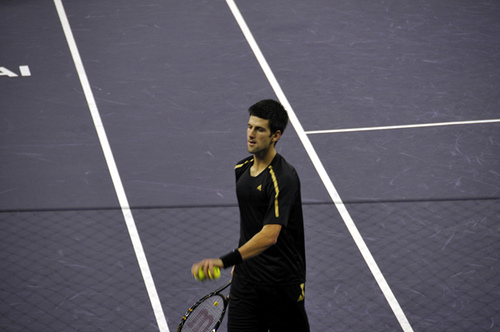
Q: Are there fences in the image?
A: Yes, there is a fence.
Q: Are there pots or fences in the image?
A: Yes, there is a fence.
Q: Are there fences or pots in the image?
A: Yes, there is a fence.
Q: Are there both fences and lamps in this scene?
A: No, there is a fence but no lamps.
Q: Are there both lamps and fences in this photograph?
A: No, there is a fence but no lamps.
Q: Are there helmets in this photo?
A: No, there are no helmets.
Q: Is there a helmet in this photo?
A: No, there are no helmets.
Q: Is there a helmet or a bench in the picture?
A: No, there are no helmets or benches.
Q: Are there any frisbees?
A: No, there are no frisbees.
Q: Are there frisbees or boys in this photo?
A: No, there are no frisbees or boys.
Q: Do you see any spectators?
A: No, there are no spectators.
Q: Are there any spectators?
A: No, there are no spectators.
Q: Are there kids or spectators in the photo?
A: No, there are no spectators or kids.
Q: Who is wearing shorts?
A: The man is wearing shorts.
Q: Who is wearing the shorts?
A: The man is wearing shorts.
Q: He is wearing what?
A: The man is wearing shorts.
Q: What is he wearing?
A: The man is wearing shorts.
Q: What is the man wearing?
A: The man is wearing shorts.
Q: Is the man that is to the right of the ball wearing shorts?
A: Yes, the man is wearing shorts.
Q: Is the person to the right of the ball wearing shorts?
A: Yes, the man is wearing shorts.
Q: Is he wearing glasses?
A: No, the man is wearing shorts.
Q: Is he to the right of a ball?
A: Yes, the man is to the right of a ball.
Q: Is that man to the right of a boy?
A: No, the man is to the right of a ball.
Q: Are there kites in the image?
A: No, there are no kites.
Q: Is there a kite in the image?
A: No, there are no kites.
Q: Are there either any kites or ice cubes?
A: No, there are no kites or ice cubes.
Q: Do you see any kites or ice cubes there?
A: No, there are no kites or ice cubes.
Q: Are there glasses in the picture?
A: No, there are no glasses.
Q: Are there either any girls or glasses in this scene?
A: No, there are no glasses or girls.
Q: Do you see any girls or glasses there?
A: No, there are no glasses or girls.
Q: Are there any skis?
A: No, there are no skis.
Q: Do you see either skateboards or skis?
A: No, there are no skis or skateboards.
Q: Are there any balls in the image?
A: Yes, there is a ball.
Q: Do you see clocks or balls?
A: Yes, there is a ball.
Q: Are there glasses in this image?
A: No, there are no glasses.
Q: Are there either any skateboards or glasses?
A: No, there are no glasses or skateboards.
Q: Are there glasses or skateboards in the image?
A: No, there are no glasses or skateboards.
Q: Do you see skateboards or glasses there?
A: No, there are no glasses or skateboards.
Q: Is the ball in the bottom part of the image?
A: Yes, the ball is in the bottom of the image.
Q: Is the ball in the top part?
A: No, the ball is in the bottom of the image.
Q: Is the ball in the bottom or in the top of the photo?
A: The ball is in the bottom of the image.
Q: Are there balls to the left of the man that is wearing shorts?
A: Yes, there is a ball to the left of the man.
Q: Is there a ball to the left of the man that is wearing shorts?
A: Yes, there is a ball to the left of the man.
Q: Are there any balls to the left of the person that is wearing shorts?
A: Yes, there is a ball to the left of the man.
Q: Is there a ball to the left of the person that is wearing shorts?
A: Yes, there is a ball to the left of the man.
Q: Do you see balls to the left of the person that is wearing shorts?
A: Yes, there is a ball to the left of the man.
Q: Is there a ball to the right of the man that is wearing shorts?
A: No, the ball is to the left of the man.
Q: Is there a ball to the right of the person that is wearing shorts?
A: No, the ball is to the left of the man.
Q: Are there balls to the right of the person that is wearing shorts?
A: No, the ball is to the left of the man.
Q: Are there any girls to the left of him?
A: No, there is a ball to the left of the man.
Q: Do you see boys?
A: No, there are no boys.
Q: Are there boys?
A: No, there are no boys.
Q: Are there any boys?
A: No, there are no boys.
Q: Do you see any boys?
A: No, there are no boys.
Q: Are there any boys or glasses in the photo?
A: No, there are no boys or glasses.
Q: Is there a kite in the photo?
A: No, there are no kites.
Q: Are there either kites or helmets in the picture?
A: No, there are no kites or helmets.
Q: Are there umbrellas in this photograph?
A: No, there are no umbrellas.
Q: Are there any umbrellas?
A: No, there are no umbrellas.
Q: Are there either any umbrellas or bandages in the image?
A: No, there are no umbrellas or bandages.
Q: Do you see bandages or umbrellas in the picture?
A: No, there are no umbrellas or bandages.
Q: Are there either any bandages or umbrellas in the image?
A: No, there are no umbrellas or bandages.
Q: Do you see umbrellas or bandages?
A: No, there are no umbrellas or bandages.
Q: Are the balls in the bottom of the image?
A: Yes, the balls are in the bottom of the image.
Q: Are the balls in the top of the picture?
A: No, the balls are in the bottom of the image.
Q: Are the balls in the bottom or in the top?
A: The balls are in the bottom of the image.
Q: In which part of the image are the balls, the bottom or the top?
A: The balls are in the bottom of the image.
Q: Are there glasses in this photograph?
A: No, there are no glasses.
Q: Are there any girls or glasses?
A: No, there are no glasses or girls.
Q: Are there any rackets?
A: Yes, there is a racket.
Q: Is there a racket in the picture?
A: Yes, there is a racket.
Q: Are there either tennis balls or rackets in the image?
A: Yes, there is a racket.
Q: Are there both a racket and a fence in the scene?
A: Yes, there are both a racket and a fence.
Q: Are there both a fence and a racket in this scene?
A: Yes, there are both a racket and a fence.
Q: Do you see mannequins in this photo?
A: No, there are no mannequins.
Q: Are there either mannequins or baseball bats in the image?
A: No, there are no mannequins or baseball bats.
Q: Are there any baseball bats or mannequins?
A: No, there are no mannequins or baseball bats.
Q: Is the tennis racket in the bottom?
A: Yes, the tennis racket is in the bottom of the image.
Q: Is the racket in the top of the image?
A: No, the racket is in the bottom of the image.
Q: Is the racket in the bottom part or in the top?
A: The racket is in the bottom of the image.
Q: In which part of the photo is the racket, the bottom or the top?
A: The racket is in the bottom of the image.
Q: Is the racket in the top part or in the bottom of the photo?
A: The racket is in the bottom of the image.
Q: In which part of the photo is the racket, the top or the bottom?
A: The racket is in the bottom of the image.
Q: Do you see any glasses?
A: No, there are no glasses.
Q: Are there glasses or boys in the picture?
A: No, there are no glasses or boys.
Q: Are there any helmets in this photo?
A: No, there are no helmets.